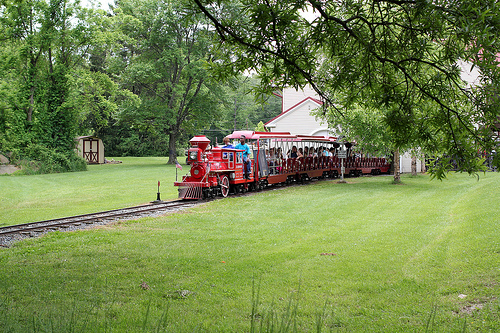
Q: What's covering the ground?
A: Grass.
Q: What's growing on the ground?
A: Grass.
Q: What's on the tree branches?
A: Leaves.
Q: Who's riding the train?
A: The people.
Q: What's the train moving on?
A: Tracks.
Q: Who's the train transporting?
A: The people.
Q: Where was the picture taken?
A: In a park.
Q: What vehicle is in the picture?
A: A train.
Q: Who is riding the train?
A: Visitors.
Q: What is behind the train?
A: A building.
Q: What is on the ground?
A: Grass.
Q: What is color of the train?
A: Red.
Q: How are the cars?
A: Open.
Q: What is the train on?
A: Tracks.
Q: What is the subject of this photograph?
A: Train.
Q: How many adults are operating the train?
A: Two.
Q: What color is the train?
A: Red.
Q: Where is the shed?
A: To the left, behind some trees.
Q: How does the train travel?
A: On rails.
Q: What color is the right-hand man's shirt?
A: Cyan.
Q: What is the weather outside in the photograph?
A: Cloudy.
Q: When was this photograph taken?
A: Daytime.